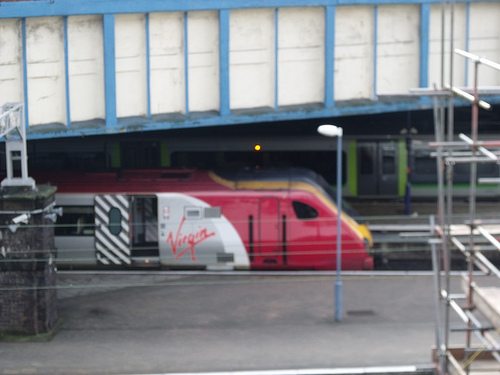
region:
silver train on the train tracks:
[55, 192, 256, 271]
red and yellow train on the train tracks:
[52, 161, 376, 282]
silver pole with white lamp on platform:
[314, 113, 348, 320]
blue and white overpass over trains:
[2, 0, 499, 131]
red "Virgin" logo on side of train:
[170, 211, 217, 265]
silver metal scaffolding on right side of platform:
[418, 43, 498, 365]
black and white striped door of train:
[88, 193, 134, 265]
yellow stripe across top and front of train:
[210, 165, 367, 247]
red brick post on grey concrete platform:
[0, 180, 67, 341]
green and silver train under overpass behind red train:
[2, 132, 498, 204]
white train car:
[53, 201, 263, 275]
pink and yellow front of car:
[248, 188, 378, 276]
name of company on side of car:
[156, 227, 221, 260]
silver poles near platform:
[442, 144, 499, 353]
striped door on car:
[88, 184, 127, 281]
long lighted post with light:
[296, 114, 353, 327]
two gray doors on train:
[343, 139, 408, 212]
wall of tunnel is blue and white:
[5, 11, 493, 106]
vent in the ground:
[342, 297, 383, 339]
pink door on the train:
[250, 187, 292, 272]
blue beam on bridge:
[18, 20, 33, 136]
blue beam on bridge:
[60, 13, 74, 128]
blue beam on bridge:
[98, 11, 120, 131]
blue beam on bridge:
[142, 14, 155, 115]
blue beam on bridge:
[181, 7, 191, 117]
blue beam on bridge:
[271, 9, 283, 109]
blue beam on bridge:
[322, 7, 338, 112]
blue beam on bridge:
[370, 3, 378, 101]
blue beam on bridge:
[418, 6, 429, 98]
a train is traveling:
[0, 165, 376, 271]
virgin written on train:
[166, 216, 216, 261]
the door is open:
[131, 198, 158, 259]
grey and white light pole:
[317, 123, 342, 322]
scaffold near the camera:
[425, 48, 498, 374]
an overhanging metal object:
[0, 103, 35, 189]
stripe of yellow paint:
[207, 170, 371, 241]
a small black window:
[292, 202, 314, 218]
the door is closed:
[257, 198, 280, 255]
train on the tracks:
[25, 155, 427, 279]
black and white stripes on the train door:
[92, 192, 129, 267]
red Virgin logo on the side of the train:
[164, 211, 220, 262]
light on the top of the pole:
[315, 122, 340, 134]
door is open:
[90, 190, 176, 271]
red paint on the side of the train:
[202, 188, 371, 268]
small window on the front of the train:
[290, 195, 320, 223]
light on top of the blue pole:
[318, 118, 352, 328]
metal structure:
[410, 46, 498, 371]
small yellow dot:
[252, 140, 262, 153]